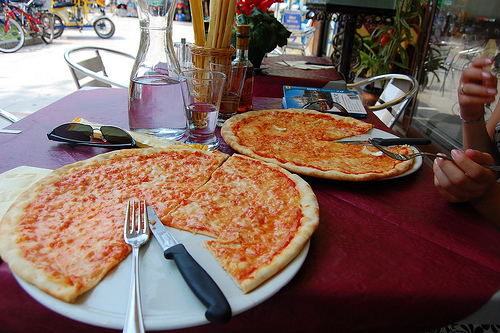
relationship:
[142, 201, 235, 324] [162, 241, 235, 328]
knife has handle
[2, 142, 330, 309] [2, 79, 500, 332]
pizza on table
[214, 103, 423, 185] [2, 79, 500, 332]
pizza on table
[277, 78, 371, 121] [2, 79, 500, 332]
book sitting on table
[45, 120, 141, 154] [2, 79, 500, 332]
sunglasses on table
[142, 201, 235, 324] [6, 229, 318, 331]
knife on plate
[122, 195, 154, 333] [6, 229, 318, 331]
fork on plate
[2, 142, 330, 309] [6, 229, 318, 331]
pizza on plate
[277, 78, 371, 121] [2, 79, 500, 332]
book on table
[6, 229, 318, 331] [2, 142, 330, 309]
plate of pizza